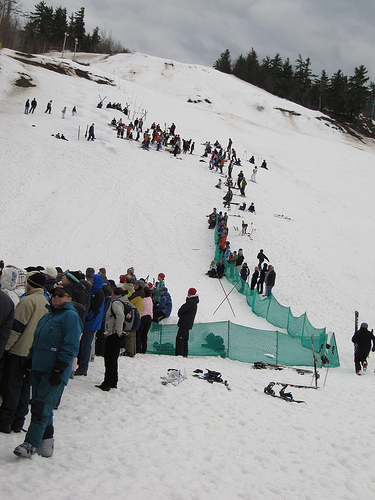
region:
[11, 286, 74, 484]
this is a person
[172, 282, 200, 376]
this is a person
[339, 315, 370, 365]
this is a person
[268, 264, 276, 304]
this is a person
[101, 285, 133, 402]
this is a person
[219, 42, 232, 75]
this is a tree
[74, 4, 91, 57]
this is a tree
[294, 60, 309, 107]
this is a tree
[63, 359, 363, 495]
this is some snow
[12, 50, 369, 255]
his is some snow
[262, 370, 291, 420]
part of a board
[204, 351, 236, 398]
part fo a cloth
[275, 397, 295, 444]
[art of a board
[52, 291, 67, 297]
The man is wearing sunglasses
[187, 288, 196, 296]
The person is wearing a hat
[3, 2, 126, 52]
Trees on the snowy hill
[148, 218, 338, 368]
A fence near the spectators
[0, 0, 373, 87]
The sky above the snowy hill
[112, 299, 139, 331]
The woman is wearing a backpack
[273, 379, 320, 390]
Skis in the snow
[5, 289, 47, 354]
The person is wearing a tan coat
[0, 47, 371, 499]
The hill is snowy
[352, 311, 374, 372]
A person running with skis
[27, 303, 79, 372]
a blue winter coat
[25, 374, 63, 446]
a pair of blue snow pants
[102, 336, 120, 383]
a black pair of pants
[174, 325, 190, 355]
a black pair of pants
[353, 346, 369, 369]
a black pair of pants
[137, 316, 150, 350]
a black pair of pants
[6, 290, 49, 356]
a tan and black winter jacket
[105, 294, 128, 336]
a grey winter coat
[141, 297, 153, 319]
a pink winter coat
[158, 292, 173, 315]
a blue and grey winter coat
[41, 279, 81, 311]
head of a person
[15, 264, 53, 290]
head of a person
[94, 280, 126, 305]
head of a person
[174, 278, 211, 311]
head of a person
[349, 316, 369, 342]
head of a person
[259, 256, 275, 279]
head of a person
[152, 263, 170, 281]
head of a person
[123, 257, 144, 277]
head of a person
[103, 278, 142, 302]
head of a person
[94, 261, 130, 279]
head of a person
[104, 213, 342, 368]
green mesh fence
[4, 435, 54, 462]
gray snow boots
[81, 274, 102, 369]
man in blue jacket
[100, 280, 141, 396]
woman in gray jacket